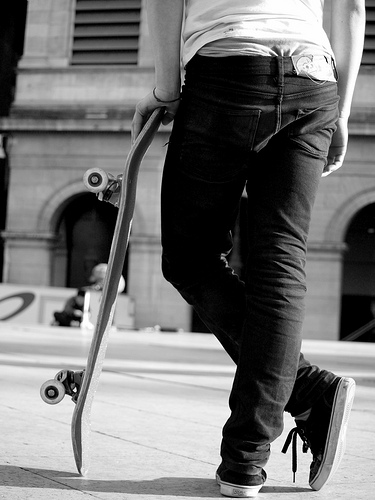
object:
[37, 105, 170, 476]
skateboard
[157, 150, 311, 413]
leg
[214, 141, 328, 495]
leg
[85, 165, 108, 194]
wheel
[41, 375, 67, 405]
wheel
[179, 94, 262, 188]
pocket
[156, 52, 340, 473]
trousers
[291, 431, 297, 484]
lace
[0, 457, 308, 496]
shadow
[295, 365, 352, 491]
shoe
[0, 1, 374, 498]
photo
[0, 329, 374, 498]
floor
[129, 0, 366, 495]
person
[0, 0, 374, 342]
building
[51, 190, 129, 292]
door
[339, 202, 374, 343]
door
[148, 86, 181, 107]
wrist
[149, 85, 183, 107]
bracelet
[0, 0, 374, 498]
background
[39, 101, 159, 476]
edge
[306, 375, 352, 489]
sole